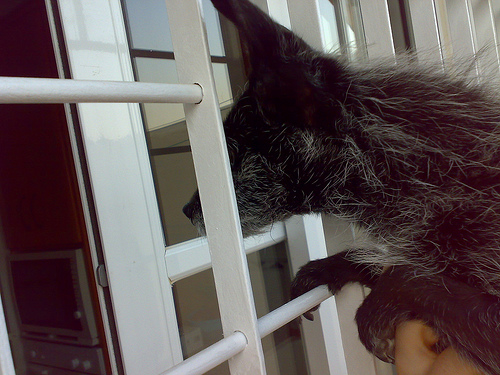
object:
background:
[0, 3, 112, 373]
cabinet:
[0, 0, 85, 255]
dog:
[170, 0, 498, 375]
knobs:
[9, 301, 98, 373]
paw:
[277, 255, 354, 323]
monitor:
[0, 247, 103, 348]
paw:
[352, 285, 451, 367]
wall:
[0, 147, 75, 239]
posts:
[175, 37, 293, 374]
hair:
[277, 54, 493, 270]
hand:
[388, 316, 496, 375]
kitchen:
[4, 1, 111, 372]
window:
[117, 1, 308, 373]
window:
[167, 266, 224, 362]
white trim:
[45, 0, 183, 373]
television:
[3, 249, 104, 350]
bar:
[0, 74, 202, 110]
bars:
[154, 37, 236, 178]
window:
[259, 313, 312, 375]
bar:
[244, 282, 348, 337]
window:
[316, 0, 345, 55]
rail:
[0, 75, 208, 106]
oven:
[5, 247, 108, 372]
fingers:
[380, 315, 440, 375]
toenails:
[299, 305, 314, 323]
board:
[166, 24, 299, 373]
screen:
[5, 258, 91, 331]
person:
[384, 312, 498, 375]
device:
[5, 243, 114, 372]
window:
[243, 237, 290, 320]